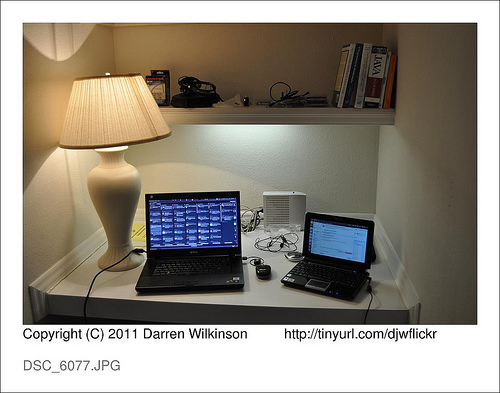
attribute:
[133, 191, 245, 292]
laptop — here, black, large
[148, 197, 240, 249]
screen — here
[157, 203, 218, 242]
display — here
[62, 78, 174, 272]
lamp — here, white, lit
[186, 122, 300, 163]
light — bright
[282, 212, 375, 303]
netbook — tiny, black, small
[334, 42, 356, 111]
book — stacked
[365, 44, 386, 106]
book — stacked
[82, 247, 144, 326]
cord — long, black, loose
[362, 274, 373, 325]
cord — loose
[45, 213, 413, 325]
desk — white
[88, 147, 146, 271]
base — white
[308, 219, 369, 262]
screen — small